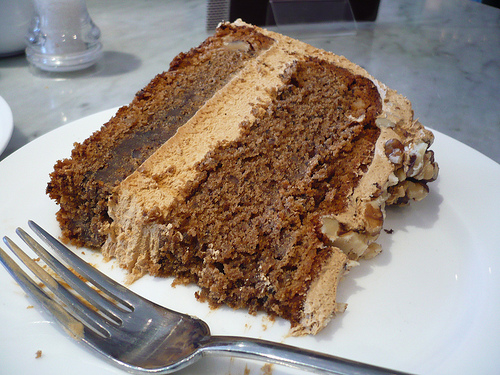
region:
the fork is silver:
[0, 220, 197, 373]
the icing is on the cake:
[375, 95, 438, 225]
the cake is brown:
[220, 181, 289, 238]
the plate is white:
[398, 193, 481, 270]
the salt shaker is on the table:
[20, 0, 106, 72]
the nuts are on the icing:
[377, 123, 442, 206]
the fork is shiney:
[16, 269, 213, 372]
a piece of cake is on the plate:
[30, 17, 443, 317]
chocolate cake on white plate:
[24, 16, 455, 317]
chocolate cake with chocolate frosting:
[41, 20, 445, 368]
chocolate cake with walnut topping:
[56, 15, 461, 355]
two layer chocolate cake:
[62, 4, 443, 356]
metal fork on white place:
[0, 215, 451, 372]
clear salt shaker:
[22, 5, 119, 75]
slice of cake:
[28, 15, 465, 312]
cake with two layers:
[52, 6, 438, 337]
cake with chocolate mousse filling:
[36, 0, 460, 369]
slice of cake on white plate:
[46, 12, 474, 333]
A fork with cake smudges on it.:
[2, 218, 406, 373]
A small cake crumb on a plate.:
[30, 349, 52, 366]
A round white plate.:
[1, 101, 498, 371]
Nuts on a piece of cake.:
[331, 120, 442, 264]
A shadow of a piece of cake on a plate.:
[332, 175, 445, 314]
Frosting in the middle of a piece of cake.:
[105, 35, 307, 270]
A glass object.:
[27, 0, 107, 77]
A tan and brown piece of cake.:
[46, 18, 442, 338]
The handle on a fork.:
[210, 327, 405, 372]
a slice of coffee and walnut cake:
[33, 13, 449, 340]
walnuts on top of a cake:
[316, 115, 439, 267]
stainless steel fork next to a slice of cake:
[2, 210, 420, 372]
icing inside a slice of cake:
[100, 35, 313, 281]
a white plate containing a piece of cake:
[2, 80, 497, 374]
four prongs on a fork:
[1, 217, 139, 348]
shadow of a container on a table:
[21, 45, 147, 80]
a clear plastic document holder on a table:
[200, 0, 385, 43]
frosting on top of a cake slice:
[290, 88, 447, 338]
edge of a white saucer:
[0, 90, 17, 171]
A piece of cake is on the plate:
[45, 0, 455, 322]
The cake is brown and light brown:
[55, 15, 449, 344]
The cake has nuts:
[329, 75, 449, 282]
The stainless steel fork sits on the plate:
[5, 209, 387, 370]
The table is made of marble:
[373, 18, 483, 101]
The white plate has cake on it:
[6, 90, 490, 362]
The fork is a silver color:
[1, 218, 345, 368]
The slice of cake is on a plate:
[50, 12, 448, 331]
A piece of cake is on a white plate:
[35, 13, 437, 318]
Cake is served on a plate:
[47, 14, 443, 337]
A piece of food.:
[194, 242, 209, 262]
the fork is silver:
[0, 219, 410, 374]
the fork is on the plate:
[0, 17, 496, 372]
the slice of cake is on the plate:
[0, 17, 498, 374]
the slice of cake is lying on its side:
[46, 15, 438, 336]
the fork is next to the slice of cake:
[0, 17, 437, 374]